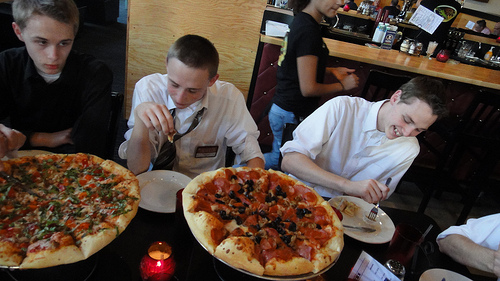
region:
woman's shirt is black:
[270, 8, 328, 108]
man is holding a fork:
[268, 51, 445, 203]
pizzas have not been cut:
[3, 126, 345, 279]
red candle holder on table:
[129, 234, 189, 279]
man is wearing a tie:
[116, 30, 267, 180]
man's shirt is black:
[5, 34, 120, 156]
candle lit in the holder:
[141, 243, 176, 270]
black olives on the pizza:
[217, 167, 324, 257]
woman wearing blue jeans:
[263, 0, 361, 162]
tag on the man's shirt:
[193, 135, 225, 172]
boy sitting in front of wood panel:
[117, 0, 260, 166]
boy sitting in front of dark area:
[1, 0, 122, 145]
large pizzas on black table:
[0, 146, 461, 276]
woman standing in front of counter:
[247, 0, 489, 205]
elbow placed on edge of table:
[426, 200, 496, 272]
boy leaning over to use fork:
[285, 71, 440, 241]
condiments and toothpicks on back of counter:
[330, 17, 455, 67]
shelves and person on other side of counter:
[295, 0, 495, 60]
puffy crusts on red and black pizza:
[181, 165, 341, 275]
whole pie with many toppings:
[2, 150, 137, 265]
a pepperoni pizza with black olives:
[183, 165, 344, 279]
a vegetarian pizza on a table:
[1, 152, 138, 272]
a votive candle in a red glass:
[141, 239, 173, 279]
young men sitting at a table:
[0, 0, 452, 201]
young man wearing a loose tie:
[151, 108, 206, 167]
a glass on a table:
[384, 210, 435, 264]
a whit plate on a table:
[139, 169, 191, 213]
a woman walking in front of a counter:
[234, 0, 359, 170]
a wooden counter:
[324, 37, 499, 92]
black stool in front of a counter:
[365, 67, 499, 232]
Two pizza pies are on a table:
[0, 152, 345, 277]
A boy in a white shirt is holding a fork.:
[278, 77, 419, 221]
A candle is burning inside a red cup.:
[138, 240, 183, 277]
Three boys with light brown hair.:
[11, 0, 451, 138]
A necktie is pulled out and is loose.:
[149, 103, 210, 170]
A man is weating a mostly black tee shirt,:
[271, 8, 331, 115]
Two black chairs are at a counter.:
[356, 66, 498, 222]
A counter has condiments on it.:
[329, 0, 499, 87]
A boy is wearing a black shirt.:
[0, 45, 112, 152]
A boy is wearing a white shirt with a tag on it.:
[122, 75, 220, 159]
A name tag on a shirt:
[193, 143, 219, 158]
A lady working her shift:
[258, 0, 361, 165]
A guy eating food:
[326, 193, 393, 243]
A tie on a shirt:
[150, 102, 205, 172]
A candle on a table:
[140, 238, 175, 280]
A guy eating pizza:
[0, 0, 120, 160]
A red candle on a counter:
[435, 48, 448, 62]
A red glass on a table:
[385, 222, 420, 276]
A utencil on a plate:
[342, 222, 376, 232]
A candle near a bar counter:
[423, 38, 440, 58]